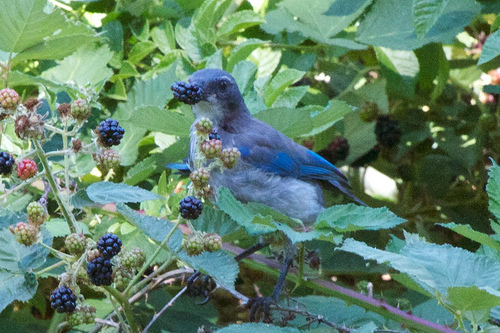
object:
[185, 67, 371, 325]
bird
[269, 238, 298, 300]
legs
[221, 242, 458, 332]
twig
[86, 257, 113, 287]
fruit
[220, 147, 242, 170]
fruit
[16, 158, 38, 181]
fruit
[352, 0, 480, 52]
leaves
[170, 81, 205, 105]
fruit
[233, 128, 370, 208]
wing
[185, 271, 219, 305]
claws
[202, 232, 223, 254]
berries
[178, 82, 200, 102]
beak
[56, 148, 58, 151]
thorns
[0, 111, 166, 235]
branch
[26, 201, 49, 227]
berries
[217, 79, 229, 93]
eye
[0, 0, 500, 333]
bush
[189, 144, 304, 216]
chest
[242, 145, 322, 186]
feathers